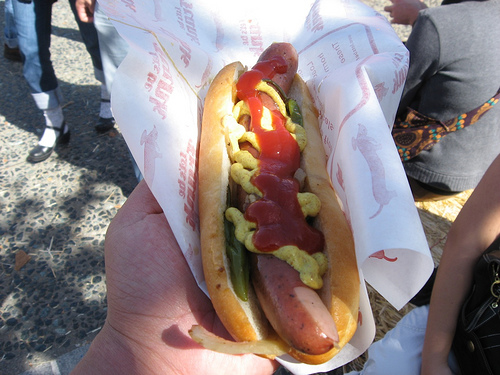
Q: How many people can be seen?
A: Four.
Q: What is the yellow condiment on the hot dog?
A: Mustard.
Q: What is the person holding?
A: A hot dog.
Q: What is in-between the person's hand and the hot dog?
A: A piece of paper.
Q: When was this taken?
A: During the day.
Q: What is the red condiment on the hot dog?
A: Ketchup.